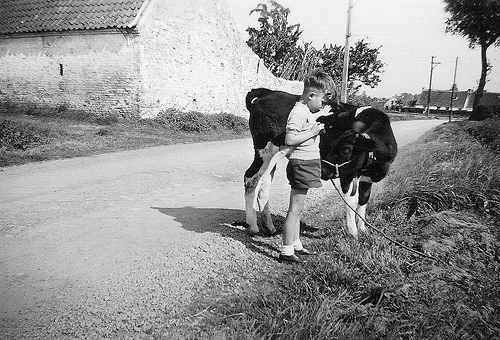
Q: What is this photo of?
A: A boy and a cow.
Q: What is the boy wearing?
A: Shirt and shorts.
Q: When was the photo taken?
A: During the day.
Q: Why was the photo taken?
A: Because it's cute.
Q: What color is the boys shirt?
A: White.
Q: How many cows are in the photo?
A: One.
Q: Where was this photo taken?
A: A country side road.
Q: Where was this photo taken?
A: On a farm.